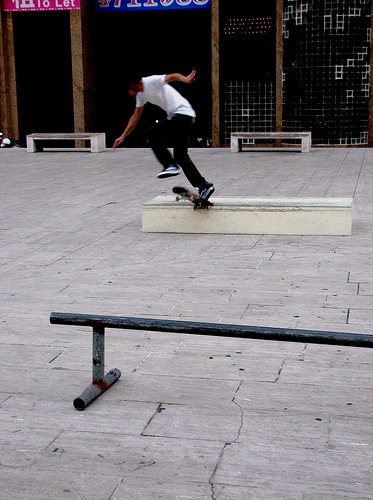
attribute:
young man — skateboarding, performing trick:
[106, 65, 216, 204]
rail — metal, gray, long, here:
[49, 308, 372, 412]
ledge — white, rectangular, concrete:
[141, 192, 351, 237]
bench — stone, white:
[227, 129, 307, 154]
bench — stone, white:
[24, 129, 110, 154]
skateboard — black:
[169, 186, 215, 213]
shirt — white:
[130, 73, 197, 120]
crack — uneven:
[189, 274, 369, 498]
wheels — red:
[172, 196, 195, 202]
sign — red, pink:
[1, 2, 81, 14]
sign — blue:
[96, 2, 213, 10]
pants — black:
[145, 112, 212, 190]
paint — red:
[82, 316, 109, 393]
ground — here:
[1, 146, 372, 499]